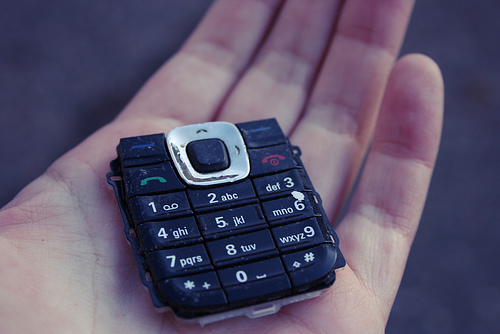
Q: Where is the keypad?
A: In the palm of the hand.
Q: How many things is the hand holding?
A: One.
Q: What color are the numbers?
A: White.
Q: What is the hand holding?
A: A Keypad.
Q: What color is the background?
A: Black.